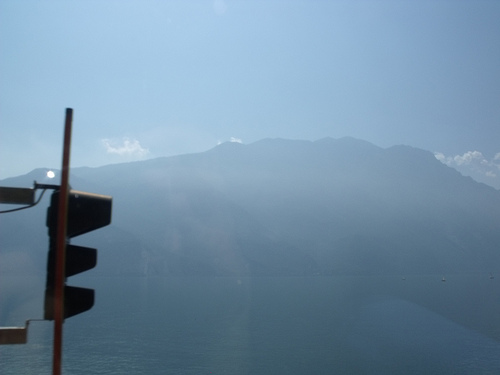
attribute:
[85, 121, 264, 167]
cloud — white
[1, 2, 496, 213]
sky — blue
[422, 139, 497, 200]
cloud — white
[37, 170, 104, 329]
light — traffic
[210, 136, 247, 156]
hill — small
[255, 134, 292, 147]
hill — small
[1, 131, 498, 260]
mountain — small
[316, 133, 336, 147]
hill — small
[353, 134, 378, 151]
hill — small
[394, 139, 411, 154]
hill — small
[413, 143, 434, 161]
hill — small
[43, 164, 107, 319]
signals — traffic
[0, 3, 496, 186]
sky — blue, clear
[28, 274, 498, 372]
water — blue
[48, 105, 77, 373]
pole — brown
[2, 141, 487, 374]
mountain — large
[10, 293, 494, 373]
water — blue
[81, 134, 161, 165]
cloud — small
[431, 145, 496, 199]
clouds — white, fluffy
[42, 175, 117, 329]
light — metal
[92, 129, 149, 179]
cloud — white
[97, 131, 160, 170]
cloud — white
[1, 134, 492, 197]
clouds — white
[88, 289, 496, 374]
water — blue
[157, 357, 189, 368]
water — blue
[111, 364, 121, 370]
water — blue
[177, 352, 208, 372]
water — blue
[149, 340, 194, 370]
water — blue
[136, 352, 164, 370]
water — blue